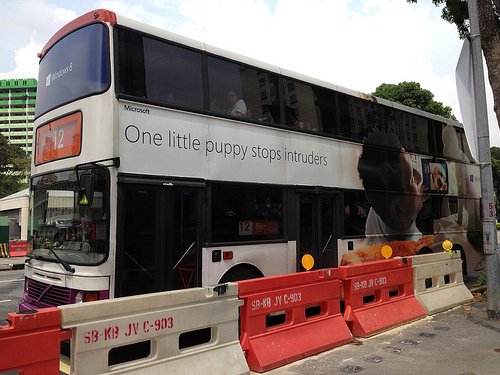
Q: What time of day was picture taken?
A: Daytime.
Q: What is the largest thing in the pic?
A: A bus.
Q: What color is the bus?
A: Red and white.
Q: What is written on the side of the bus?
A: One little puppy stops intruders.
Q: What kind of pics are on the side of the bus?
A: Pics of dogs.